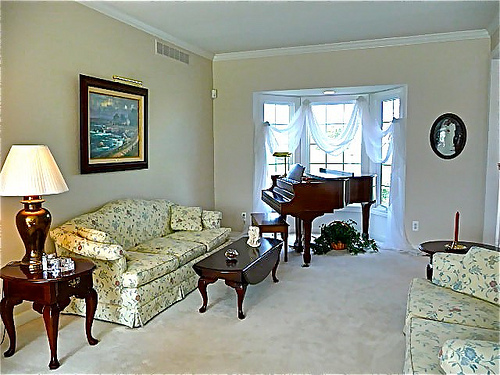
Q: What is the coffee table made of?
A: Wood.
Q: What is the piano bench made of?
A: Wood.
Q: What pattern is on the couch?
A: Flower.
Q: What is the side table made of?
A: Wood.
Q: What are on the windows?
A: Curtains.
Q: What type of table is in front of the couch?
A: A coffee table.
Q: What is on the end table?
A: A lamp.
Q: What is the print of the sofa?
A: Floral.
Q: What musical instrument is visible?
A: Piano.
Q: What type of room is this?
A: Livingroom.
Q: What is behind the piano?
A: Window.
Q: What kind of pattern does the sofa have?
A: Floral.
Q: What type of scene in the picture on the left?
A: Beach.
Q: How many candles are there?
A: 1.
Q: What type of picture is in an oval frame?
A: Wedding picture.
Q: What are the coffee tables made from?
A: Wood.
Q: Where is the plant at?
A: Under the piano.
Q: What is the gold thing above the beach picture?
A: Light.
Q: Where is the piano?
A: In the room.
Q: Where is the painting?
A: On the wall.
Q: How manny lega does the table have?
A: Four.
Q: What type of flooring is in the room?
A: Carpet.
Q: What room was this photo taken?
A: Living room.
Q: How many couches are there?
A: Two.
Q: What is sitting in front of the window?
A: Piano.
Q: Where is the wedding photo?
A: Next to window.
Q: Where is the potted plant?
A: Under the piano.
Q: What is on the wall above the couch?
A: Photo.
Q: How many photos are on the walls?
A: Two.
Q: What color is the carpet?
A: White.